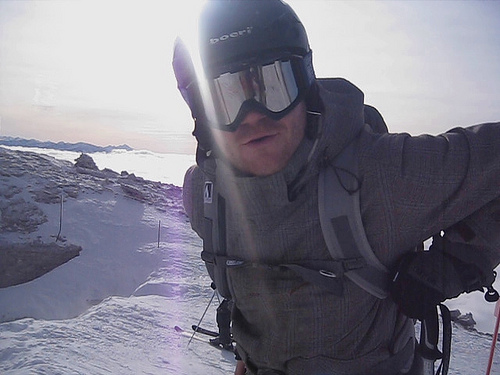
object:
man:
[170, 2, 499, 375]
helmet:
[167, 0, 324, 151]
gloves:
[389, 264, 444, 320]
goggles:
[184, 57, 307, 133]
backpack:
[322, 103, 426, 314]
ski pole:
[184, 288, 219, 347]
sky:
[3, 2, 500, 153]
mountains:
[2, 135, 130, 158]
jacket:
[180, 77, 499, 375]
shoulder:
[355, 126, 448, 193]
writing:
[207, 24, 256, 47]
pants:
[214, 298, 233, 345]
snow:
[10, 307, 154, 373]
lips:
[237, 133, 279, 146]